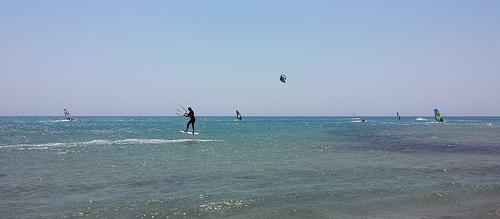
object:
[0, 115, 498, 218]
water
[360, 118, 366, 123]
person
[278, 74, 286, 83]
kite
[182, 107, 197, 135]
man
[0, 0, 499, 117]
sky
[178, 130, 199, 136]
kiteboard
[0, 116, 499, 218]
wave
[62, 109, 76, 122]
boat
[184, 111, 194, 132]
wetsuit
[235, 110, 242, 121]
boat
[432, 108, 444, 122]
boat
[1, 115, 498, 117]
skyline